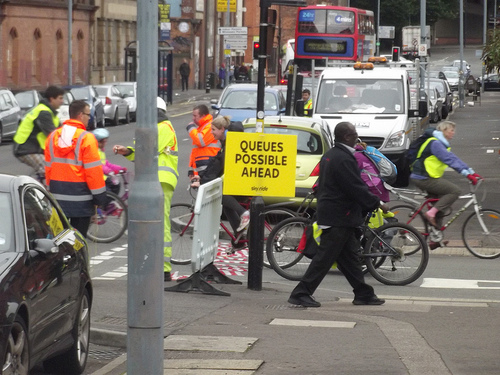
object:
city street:
[1, 0, 500, 375]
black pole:
[248, 0, 268, 291]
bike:
[266, 188, 428, 286]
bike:
[388, 177, 498, 258]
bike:
[168, 181, 307, 268]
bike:
[33, 171, 127, 243]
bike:
[295, 181, 429, 255]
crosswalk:
[375, 239, 497, 309]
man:
[410, 119, 481, 234]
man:
[185, 104, 221, 183]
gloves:
[468, 173, 479, 186]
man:
[288, 120, 384, 308]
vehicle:
[208, 82, 286, 125]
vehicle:
[270, 80, 319, 117]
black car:
[1, 173, 94, 373]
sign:
[222, 129, 297, 197]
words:
[234, 139, 287, 179]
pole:
[255, 10, 274, 73]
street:
[0, 34, 499, 372]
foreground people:
[10, 80, 481, 309]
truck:
[304, 60, 418, 182]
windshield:
[312, 74, 407, 116]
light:
[254, 41, 260, 59]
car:
[0, 89, 23, 145]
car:
[10, 88, 45, 124]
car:
[88, 79, 130, 126]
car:
[110, 81, 169, 118]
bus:
[295, 4, 377, 64]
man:
[113, 96, 177, 281]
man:
[11, 85, 62, 187]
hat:
[38, 79, 72, 98]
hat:
[151, 95, 168, 110]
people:
[350, 146, 392, 203]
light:
[391, 45, 401, 63]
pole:
[244, 199, 263, 289]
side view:
[316, 116, 372, 296]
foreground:
[0, 172, 498, 364]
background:
[0, 0, 500, 80]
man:
[46, 99, 105, 238]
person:
[189, 117, 251, 250]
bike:
[169, 173, 306, 269]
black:
[314, 170, 351, 229]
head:
[333, 122, 359, 150]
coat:
[43, 119, 107, 216]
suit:
[296, 136, 381, 300]